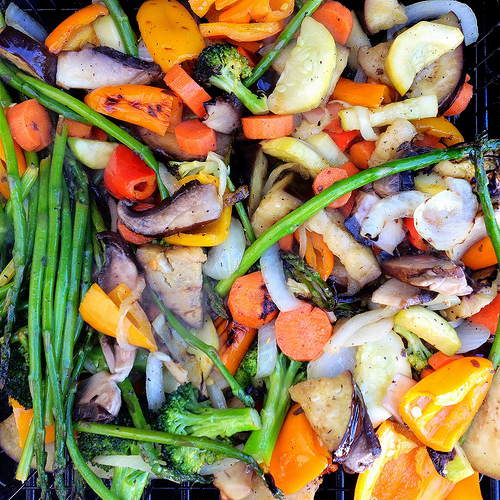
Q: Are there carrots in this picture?
A: Yes, there is a carrot.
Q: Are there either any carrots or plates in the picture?
A: Yes, there is a carrot.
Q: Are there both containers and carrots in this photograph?
A: No, there is a carrot but no containers.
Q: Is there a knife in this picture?
A: No, there are no knives.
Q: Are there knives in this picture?
A: No, there are no knives.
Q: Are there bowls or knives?
A: No, there are no knives or bowls.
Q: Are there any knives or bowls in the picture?
A: No, there are no knives or bowls.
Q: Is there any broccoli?
A: Yes, there is broccoli.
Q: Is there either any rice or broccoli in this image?
A: Yes, there is broccoli.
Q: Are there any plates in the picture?
A: No, there are no plates.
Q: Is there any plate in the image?
A: No, there are no plates.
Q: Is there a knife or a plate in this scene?
A: No, there are no plates or knives.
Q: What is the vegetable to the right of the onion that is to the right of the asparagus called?
A: The vegetable is broccoli.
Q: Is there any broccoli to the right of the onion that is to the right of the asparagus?
A: Yes, there is broccoli to the right of the onion.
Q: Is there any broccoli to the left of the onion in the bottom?
A: No, the broccoli is to the right of the onion.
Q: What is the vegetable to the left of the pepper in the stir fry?
A: The vegetable is broccoli.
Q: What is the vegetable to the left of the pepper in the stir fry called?
A: The vegetable is broccoli.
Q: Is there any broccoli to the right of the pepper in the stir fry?
A: No, the broccoli is to the left of the pepper.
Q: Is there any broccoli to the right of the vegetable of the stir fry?
A: Yes, there is broccoli to the right of the vegetable.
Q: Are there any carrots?
A: Yes, there is a carrot.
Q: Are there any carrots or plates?
A: Yes, there is a carrot.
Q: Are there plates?
A: No, there are no plates.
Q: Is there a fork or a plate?
A: No, there are no plates or forks.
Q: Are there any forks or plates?
A: No, there are no plates or forks.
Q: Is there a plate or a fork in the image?
A: No, there are no plates or forks.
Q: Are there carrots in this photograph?
A: Yes, there is a carrot.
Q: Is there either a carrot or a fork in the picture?
A: Yes, there is a carrot.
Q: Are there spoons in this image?
A: No, there are no spoons.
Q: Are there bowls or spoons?
A: No, there are no spoons or bowls.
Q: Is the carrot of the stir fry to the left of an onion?
A: Yes, the carrot is to the left of an onion.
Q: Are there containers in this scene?
A: No, there are no containers.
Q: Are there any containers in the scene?
A: No, there are no containers.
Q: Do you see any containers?
A: No, there are no containers.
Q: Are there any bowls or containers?
A: No, there are no containers or bowls.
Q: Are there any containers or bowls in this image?
A: No, there are no containers or bowls.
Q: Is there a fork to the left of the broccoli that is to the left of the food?
A: No, there is a vegetable to the left of the broccoli.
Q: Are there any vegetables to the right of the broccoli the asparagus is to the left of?
A: Yes, there is a vegetable to the right of the broccoli.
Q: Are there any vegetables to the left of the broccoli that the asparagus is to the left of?
A: No, the vegetable is to the right of the broccoli.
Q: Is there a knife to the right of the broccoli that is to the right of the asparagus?
A: No, there is a vegetable to the right of the broccoli.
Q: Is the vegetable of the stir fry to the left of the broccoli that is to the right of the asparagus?
A: No, the vegetable is to the right of the broccoli.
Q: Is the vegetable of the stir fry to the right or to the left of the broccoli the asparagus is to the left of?
A: The vegetable is to the right of the broccoli.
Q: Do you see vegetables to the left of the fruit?
A: Yes, there is a vegetable to the left of the fruit.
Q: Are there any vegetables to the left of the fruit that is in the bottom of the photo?
A: Yes, there is a vegetable to the left of the fruit.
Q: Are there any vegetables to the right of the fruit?
A: No, the vegetable is to the left of the fruit.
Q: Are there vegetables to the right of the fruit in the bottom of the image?
A: No, the vegetable is to the left of the fruit.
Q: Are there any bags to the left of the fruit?
A: No, there is a vegetable to the left of the fruit.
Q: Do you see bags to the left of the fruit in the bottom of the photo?
A: No, there is a vegetable to the left of the fruit.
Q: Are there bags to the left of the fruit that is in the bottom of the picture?
A: No, there is a vegetable to the left of the fruit.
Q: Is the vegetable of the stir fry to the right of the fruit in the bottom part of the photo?
A: No, the vegetable is to the left of the fruit.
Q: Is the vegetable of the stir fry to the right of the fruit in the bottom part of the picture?
A: No, the vegetable is to the left of the fruit.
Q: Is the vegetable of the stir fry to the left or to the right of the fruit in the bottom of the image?
A: The vegetable is to the left of the fruit.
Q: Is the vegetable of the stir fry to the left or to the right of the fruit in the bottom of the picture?
A: The vegetable is to the left of the fruit.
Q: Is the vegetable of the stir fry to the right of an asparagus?
A: Yes, the vegetable is to the right of an asparagus.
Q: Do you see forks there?
A: No, there are no forks.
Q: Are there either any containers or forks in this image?
A: No, there are no forks or containers.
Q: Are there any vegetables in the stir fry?
A: Yes, there is a vegetable in the stir fry.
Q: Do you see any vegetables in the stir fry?
A: Yes, there is a vegetable in the stir fry.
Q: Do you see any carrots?
A: Yes, there is a carrot.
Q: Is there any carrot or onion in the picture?
A: Yes, there is a carrot.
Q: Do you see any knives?
A: No, there are no knives.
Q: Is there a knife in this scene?
A: No, there are no knives.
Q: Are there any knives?
A: No, there are no knives.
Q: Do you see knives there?
A: No, there are no knives.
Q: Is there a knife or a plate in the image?
A: No, there are no knives or plates.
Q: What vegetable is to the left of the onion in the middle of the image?
A: The vegetable is a carrot.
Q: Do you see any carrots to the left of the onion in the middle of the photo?
A: Yes, there is a carrot to the left of the onion.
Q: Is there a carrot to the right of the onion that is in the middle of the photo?
A: No, the carrot is to the left of the onion.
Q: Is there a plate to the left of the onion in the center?
A: No, there is a carrot to the left of the onion.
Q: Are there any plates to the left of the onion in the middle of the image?
A: No, there is a carrot to the left of the onion.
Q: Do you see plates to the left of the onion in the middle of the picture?
A: No, there is a carrot to the left of the onion.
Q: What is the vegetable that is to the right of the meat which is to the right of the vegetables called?
A: The vegetable is a carrot.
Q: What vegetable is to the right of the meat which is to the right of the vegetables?
A: The vegetable is a carrot.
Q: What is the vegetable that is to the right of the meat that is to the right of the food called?
A: The vegetable is a carrot.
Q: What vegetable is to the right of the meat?
A: The vegetable is a carrot.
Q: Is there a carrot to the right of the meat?
A: Yes, there is a carrot to the right of the meat.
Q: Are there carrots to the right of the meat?
A: Yes, there is a carrot to the right of the meat.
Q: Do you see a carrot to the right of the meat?
A: Yes, there is a carrot to the right of the meat.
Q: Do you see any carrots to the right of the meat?
A: Yes, there is a carrot to the right of the meat.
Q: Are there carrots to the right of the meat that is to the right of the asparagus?
A: Yes, there is a carrot to the right of the meat.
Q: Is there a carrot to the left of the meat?
A: No, the carrot is to the right of the meat.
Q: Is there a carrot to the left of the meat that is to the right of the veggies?
A: No, the carrot is to the right of the meat.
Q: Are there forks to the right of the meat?
A: No, there is a carrot to the right of the meat.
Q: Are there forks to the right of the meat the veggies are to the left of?
A: No, there is a carrot to the right of the meat.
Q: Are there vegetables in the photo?
A: Yes, there are vegetables.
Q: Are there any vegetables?
A: Yes, there are vegetables.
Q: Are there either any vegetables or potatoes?
A: Yes, there are vegetables.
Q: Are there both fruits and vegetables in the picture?
A: Yes, there are both vegetables and a fruit.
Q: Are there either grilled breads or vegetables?
A: Yes, there are grilled vegetables.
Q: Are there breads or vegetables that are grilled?
A: Yes, the vegetables are grilled.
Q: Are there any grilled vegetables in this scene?
A: Yes, there are grilled vegetables.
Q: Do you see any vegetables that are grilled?
A: Yes, there are vegetables that are grilled.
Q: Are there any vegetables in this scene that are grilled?
A: Yes, there are vegetables that are grilled.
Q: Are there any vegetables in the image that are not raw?
A: Yes, there are grilled vegetables.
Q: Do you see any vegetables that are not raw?
A: Yes, there are grilled vegetables.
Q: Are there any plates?
A: No, there are no plates.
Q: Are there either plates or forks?
A: No, there are no plates or forks.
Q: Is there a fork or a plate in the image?
A: No, there are no plates or forks.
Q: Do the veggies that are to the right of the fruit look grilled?
A: Yes, the veggies are grilled.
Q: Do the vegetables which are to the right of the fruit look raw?
A: No, the veggies are grilled.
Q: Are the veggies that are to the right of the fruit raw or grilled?
A: The vegetables are grilled.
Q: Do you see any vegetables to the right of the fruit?
A: Yes, there are vegetables to the right of the fruit.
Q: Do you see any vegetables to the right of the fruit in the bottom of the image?
A: Yes, there are vegetables to the right of the fruit.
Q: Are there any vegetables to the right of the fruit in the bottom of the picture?
A: Yes, there are vegetables to the right of the fruit.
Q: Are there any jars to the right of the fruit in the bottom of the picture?
A: No, there are vegetables to the right of the fruit.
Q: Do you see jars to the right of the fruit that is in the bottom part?
A: No, there are vegetables to the right of the fruit.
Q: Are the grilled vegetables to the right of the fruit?
A: Yes, the veggies are to the right of the fruit.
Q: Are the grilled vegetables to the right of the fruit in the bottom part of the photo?
A: Yes, the veggies are to the right of the fruit.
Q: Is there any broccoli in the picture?
A: Yes, there is broccoli.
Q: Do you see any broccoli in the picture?
A: Yes, there is broccoli.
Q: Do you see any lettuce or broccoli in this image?
A: Yes, there is broccoli.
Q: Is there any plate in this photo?
A: No, there are no plates.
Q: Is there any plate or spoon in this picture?
A: No, there are no plates or spoons.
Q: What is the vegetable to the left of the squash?
A: The vegetable is broccoli.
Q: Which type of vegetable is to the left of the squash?
A: The vegetable is broccoli.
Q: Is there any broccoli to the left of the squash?
A: Yes, there is broccoli to the left of the squash.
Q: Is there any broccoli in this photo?
A: Yes, there is broccoli.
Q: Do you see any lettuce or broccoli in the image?
A: Yes, there is broccoli.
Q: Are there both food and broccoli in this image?
A: Yes, there are both broccoli and food.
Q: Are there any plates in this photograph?
A: No, there are no plates.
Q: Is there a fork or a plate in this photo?
A: No, there are no plates or forks.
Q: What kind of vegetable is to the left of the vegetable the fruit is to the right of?
A: The vegetable is broccoli.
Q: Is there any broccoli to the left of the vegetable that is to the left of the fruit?
A: Yes, there is broccoli to the left of the vegetable.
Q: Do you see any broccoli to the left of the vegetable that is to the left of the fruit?
A: Yes, there is broccoli to the left of the vegetable.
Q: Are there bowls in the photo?
A: No, there are no bowls.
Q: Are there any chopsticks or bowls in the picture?
A: No, there are no bowls or chopsticks.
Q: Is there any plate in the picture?
A: No, there are no plates.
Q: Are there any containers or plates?
A: No, there are no plates or containers.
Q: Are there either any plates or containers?
A: No, there are no plates or containers.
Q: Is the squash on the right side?
A: Yes, the squash is on the right of the image.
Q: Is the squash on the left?
A: No, the squash is on the right of the image.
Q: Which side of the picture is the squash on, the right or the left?
A: The squash is on the right of the image.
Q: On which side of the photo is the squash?
A: The squash is on the right of the image.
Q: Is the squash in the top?
A: Yes, the squash is in the top of the image.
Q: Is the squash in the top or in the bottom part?
A: The squash is in the top of the image.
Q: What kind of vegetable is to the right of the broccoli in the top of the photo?
A: The vegetable is a squash.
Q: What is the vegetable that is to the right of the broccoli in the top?
A: The vegetable is a squash.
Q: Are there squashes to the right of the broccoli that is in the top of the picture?
A: Yes, there is a squash to the right of the broccoli.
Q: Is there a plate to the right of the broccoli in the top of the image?
A: No, there is a squash to the right of the broccoli.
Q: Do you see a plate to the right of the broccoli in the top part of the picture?
A: No, there is a squash to the right of the broccoli.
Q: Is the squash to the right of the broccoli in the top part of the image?
A: Yes, the squash is to the right of the broccoli.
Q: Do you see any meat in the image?
A: Yes, there is meat.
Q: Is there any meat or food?
A: Yes, there is meat.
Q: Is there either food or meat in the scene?
A: Yes, there is meat.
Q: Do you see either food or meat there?
A: Yes, there is meat.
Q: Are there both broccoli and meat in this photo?
A: Yes, there are both meat and broccoli.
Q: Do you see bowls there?
A: No, there are no bowls.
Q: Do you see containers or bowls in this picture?
A: No, there are no bowls or containers.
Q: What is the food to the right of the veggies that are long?
A: The food is meat.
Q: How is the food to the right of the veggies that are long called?
A: The food is meat.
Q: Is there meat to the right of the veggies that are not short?
A: Yes, there is meat to the right of the vegetables.